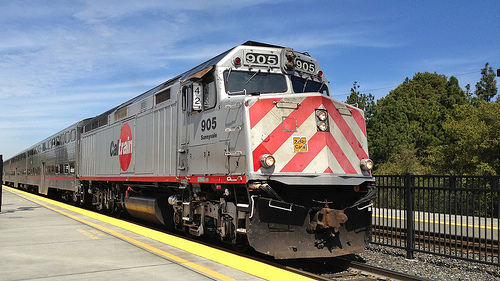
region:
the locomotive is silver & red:
[64, 35, 370, 245]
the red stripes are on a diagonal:
[251, 102, 376, 189]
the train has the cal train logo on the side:
[105, 124, 140, 179]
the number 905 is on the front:
[241, 50, 282, 74]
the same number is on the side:
[197, 115, 235, 142]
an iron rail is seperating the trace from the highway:
[388, 165, 497, 263]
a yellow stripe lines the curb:
[8, 186, 315, 277]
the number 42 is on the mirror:
[187, 82, 207, 116]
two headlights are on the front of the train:
[317, 104, 330, 139]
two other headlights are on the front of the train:
[256, 152, 386, 174]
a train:
[90, 66, 356, 260]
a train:
[169, 116, 291, 266]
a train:
[129, 9, 286, 219]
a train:
[114, 135, 212, 200]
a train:
[132, 89, 256, 211]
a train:
[103, 94, 243, 274]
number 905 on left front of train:
[238, 47, 289, 82]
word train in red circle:
[115, 126, 162, 192]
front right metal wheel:
[217, 206, 247, 247]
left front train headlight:
[360, 148, 389, 175]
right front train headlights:
[253, 149, 280, 173]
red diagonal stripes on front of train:
[259, 101, 309, 158]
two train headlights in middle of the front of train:
[306, 110, 350, 149]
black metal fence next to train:
[390, 181, 491, 255]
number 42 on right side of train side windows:
[185, 85, 212, 112]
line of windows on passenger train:
[34, 135, 76, 155]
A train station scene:
[0, 10, 494, 277]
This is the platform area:
[5, 185, 222, 279]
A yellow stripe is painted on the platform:
[70, 195, 196, 258]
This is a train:
[11, 42, 387, 266]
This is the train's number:
[194, 114, 229, 141]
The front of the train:
[226, 31, 386, 258]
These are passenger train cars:
[3, 114, 85, 200]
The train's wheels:
[166, 188, 243, 245]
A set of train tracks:
[292, 242, 420, 279]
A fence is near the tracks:
[386, 159, 496, 278]